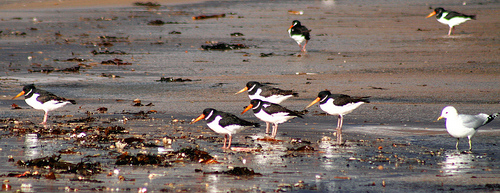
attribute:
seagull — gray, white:
[425, 94, 498, 153]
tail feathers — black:
[478, 109, 497, 127]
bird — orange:
[231, 92, 308, 139]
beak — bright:
[235, 94, 263, 123]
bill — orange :
[298, 94, 326, 124]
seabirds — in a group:
[5, 6, 493, 156]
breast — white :
[198, 115, 229, 142]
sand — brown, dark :
[4, 1, 497, 156]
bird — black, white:
[424, 4, 477, 35]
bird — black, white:
[285, 18, 311, 50]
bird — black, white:
[12, 81, 74, 123]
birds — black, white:
[189, 80, 371, 151]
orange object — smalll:
[368, 140, 389, 155]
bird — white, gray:
[434, 102, 498, 150]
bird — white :
[437, 104, 499, 156]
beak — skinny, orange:
[192, 114, 205, 123]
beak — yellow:
[435, 113, 444, 123]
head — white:
[441, 103, 458, 119]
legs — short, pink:
[331, 112, 349, 138]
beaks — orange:
[184, 111, 213, 129]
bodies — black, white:
[256, 71, 371, 157]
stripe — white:
[322, 89, 330, 100]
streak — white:
[178, 96, 264, 150]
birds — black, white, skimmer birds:
[162, 61, 382, 169]